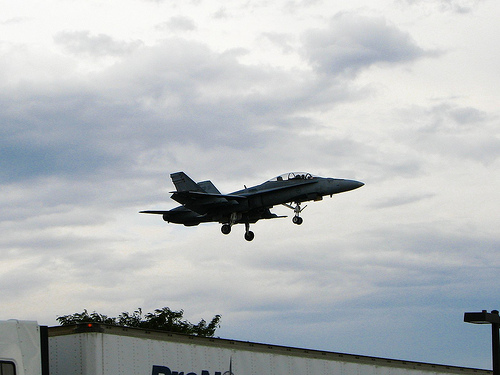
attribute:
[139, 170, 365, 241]
plane — jet, f18, landing, flying, low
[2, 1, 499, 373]
clouds — white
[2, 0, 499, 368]
sky — blue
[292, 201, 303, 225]
landing gear — extended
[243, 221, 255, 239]
landing gear — extended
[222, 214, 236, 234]
landing gear — extended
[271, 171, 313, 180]
cockpit — glass, clear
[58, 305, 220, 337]
tree — growing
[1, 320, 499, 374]
truck — white, metal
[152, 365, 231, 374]
writing — black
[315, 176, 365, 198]
nose — pointed